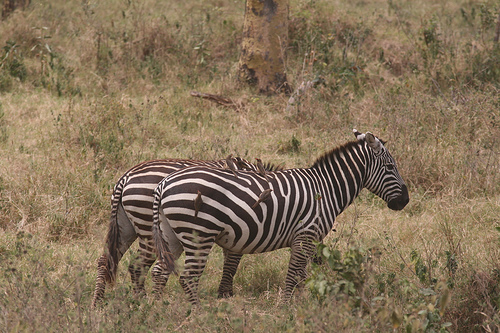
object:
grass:
[303, 241, 367, 307]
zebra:
[154, 143, 429, 291]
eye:
[384, 162, 395, 171]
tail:
[146, 193, 174, 273]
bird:
[251, 189, 273, 208]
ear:
[352, 129, 379, 147]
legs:
[179, 226, 208, 305]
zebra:
[94, 163, 153, 301]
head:
[344, 128, 410, 212]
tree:
[215, 0, 301, 101]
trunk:
[253, 3, 278, 78]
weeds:
[308, 247, 359, 302]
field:
[0, 1, 500, 127]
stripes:
[224, 176, 324, 233]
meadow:
[0, 51, 93, 312]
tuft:
[155, 237, 165, 263]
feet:
[279, 282, 299, 305]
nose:
[402, 183, 409, 210]